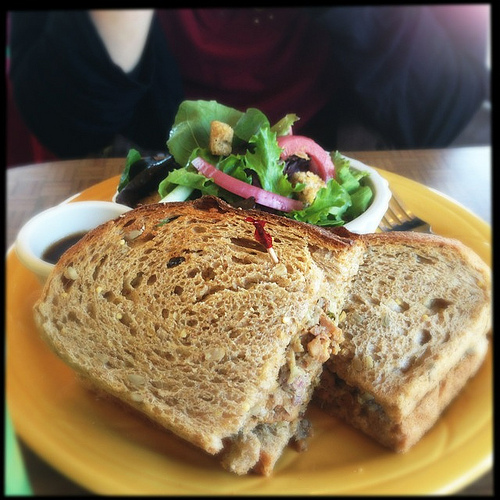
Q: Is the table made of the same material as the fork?
A: No, the table is made of wood and the fork is made of metal.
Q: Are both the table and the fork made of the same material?
A: No, the table is made of wood and the fork is made of metal.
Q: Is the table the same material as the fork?
A: No, the table is made of wood and the fork is made of metal.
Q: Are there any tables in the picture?
A: Yes, there is a table.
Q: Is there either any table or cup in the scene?
A: Yes, there is a table.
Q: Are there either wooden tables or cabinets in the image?
A: Yes, there is a wood table.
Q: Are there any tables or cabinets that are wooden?
A: Yes, the table is wooden.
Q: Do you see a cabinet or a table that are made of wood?
A: Yes, the table is made of wood.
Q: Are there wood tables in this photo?
A: Yes, there is a wood table.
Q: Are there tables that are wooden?
A: Yes, there is a table that is wooden.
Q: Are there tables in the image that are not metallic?
A: Yes, there is a wooden table.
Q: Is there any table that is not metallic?
A: Yes, there is a wooden table.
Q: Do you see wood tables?
A: Yes, there is a table that is made of wood.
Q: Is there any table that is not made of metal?
A: Yes, there is a table that is made of wood.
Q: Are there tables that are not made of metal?
A: Yes, there is a table that is made of wood.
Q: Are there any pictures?
A: No, there are no pictures.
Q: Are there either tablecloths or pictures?
A: No, there are no pictures or tablecloths.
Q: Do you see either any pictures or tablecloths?
A: No, there are no pictures or tablecloths.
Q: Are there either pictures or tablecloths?
A: No, there are no pictures or tablecloths.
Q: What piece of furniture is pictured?
A: The piece of furniture is a table.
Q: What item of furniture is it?
A: The piece of furniture is a table.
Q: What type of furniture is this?
A: This is a table.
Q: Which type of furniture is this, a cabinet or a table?
A: This is a table.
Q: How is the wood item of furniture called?
A: The piece of furniture is a table.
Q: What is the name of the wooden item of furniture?
A: The piece of furniture is a table.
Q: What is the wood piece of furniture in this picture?
A: The piece of furniture is a table.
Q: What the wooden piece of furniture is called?
A: The piece of furniture is a table.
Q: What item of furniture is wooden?
A: The piece of furniture is a table.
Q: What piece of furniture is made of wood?
A: The piece of furniture is a table.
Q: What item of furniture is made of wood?
A: The piece of furniture is a table.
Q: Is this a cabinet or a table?
A: This is a table.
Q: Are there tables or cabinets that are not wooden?
A: No, there is a table but it is wooden.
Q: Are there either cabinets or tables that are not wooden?
A: No, there is a table but it is wooden.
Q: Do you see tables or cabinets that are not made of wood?
A: No, there is a table but it is made of wood.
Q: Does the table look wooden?
A: Yes, the table is wooden.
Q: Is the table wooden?
A: Yes, the table is wooden.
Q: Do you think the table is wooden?
A: Yes, the table is wooden.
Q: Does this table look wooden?
A: Yes, the table is wooden.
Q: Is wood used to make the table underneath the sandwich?
A: Yes, the table is made of wood.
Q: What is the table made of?
A: The table is made of wood.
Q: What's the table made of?
A: The table is made of wood.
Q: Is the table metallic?
A: No, the table is wooden.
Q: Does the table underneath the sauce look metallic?
A: No, the table is wooden.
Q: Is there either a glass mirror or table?
A: No, there is a table but it is wooden.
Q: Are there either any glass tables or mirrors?
A: No, there is a table but it is wooden.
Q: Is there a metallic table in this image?
A: No, there is a table but it is wooden.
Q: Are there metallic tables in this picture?
A: No, there is a table but it is wooden.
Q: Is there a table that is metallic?
A: No, there is a table but it is wooden.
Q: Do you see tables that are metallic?
A: No, there is a table but it is wooden.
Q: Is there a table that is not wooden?
A: No, there is a table but it is wooden.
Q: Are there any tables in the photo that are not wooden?
A: No, there is a table but it is wooden.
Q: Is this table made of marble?
A: No, the table is made of wood.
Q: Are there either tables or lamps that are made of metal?
A: No, there is a table but it is made of wood.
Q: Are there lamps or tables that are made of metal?
A: No, there is a table but it is made of wood.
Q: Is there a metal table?
A: No, there is a table but it is made of wood.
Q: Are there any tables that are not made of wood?
A: No, there is a table but it is made of wood.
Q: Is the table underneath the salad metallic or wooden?
A: The table is wooden.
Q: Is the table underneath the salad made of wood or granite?
A: The table is made of wood.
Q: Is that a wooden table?
A: Yes, that is a wooden table.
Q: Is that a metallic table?
A: No, that is a wooden table.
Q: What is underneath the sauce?
A: The table is underneath the sauce.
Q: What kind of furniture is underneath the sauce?
A: The piece of furniture is a table.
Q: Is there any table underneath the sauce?
A: Yes, there is a table underneath the sauce.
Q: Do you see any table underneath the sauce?
A: Yes, there is a table underneath the sauce.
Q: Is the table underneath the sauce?
A: Yes, the table is underneath the sauce.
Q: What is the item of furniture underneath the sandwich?
A: The piece of furniture is a table.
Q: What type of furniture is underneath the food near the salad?
A: The piece of furniture is a table.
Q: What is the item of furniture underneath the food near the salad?
A: The piece of furniture is a table.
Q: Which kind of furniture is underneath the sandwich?
A: The piece of furniture is a table.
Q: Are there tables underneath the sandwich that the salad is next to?
A: Yes, there is a table underneath the sandwich.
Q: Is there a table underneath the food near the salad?
A: Yes, there is a table underneath the sandwich.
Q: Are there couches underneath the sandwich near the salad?
A: No, there is a table underneath the sandwich.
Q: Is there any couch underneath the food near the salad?
A: No, there is a table underneath the sandwich.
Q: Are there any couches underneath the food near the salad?
A: No, there is a table underneath the sandwich.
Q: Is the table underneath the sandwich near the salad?
A: Yes, the table is underneath the sandwich.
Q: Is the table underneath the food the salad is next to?
A: Yes, the table is underneath the sandwich.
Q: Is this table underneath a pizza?
A: No, the table is underneath the sandwich.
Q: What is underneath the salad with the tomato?
A: The table is underneath the salad.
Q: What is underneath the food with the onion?
A: The table is underneath the salad.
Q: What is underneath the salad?
A: The table is underneath the salad.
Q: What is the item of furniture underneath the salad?
A: The piece of furniture is a table.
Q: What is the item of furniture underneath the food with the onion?
A: The piece of furniture is a table.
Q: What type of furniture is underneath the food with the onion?
A: The piece of furniture is a table.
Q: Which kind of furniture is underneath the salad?
A: The piece of furniture is a table.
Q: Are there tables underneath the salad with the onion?
A: Yes, there is a table underneath the salad.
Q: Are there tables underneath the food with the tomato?
A: Yes, there is a table underneath the salad.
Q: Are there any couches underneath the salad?
A: No, there is a table underneath the salad.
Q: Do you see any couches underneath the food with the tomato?
A: No, there is a table underneath the salad.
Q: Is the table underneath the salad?
A: Yes, the table is underneath the salad.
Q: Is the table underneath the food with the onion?
A: Yes, the table is underneath the salad.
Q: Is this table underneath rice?
A: No, the table is underneath the salad.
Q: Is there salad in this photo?
A: Yes, there is salad.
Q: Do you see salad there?
A: Yes, there is salad.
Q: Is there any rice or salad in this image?
A: Yes, there is salad.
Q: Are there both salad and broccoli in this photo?
A: No, there is salad but no broccoli.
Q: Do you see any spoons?
A: No, there are no spoons.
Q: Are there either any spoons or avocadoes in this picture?
A: No, there are no spoons or avocadoes.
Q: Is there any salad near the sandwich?
A: Yes, there is salad near the sandwich.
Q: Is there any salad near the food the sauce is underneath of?
A: Yes, there is salad near the sandwich.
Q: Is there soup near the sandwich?
A: No, there is salad near the sandwich.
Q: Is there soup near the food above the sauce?
A: No, there is salad near the sandwich.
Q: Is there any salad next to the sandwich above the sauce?
A: Yes, there is salad next to the sandwich.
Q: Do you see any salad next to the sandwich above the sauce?
A: Yes, there is salad next to the sandwich.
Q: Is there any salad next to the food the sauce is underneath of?
A: Yes, there is salad next to the sandwich.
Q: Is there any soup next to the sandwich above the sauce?
A: No, there is salad next to the sandwich.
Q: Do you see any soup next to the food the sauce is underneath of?
A: No, there is salad next to the sandwich.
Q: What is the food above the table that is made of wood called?
A: The food is salad.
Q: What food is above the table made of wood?
A: The food is salad.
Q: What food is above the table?
A: The food is salad.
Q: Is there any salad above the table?
A: Yes, there is salad above the table.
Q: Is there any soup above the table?
A: No, there is salad above the table.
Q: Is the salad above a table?
A: Yes, the salad is above a table.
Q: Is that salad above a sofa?
A: No, the salad is above a table.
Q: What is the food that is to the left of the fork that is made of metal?
A: The food is salad.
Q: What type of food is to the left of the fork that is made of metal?
A: The food is salad.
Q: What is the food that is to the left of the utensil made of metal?
A: The food is salad.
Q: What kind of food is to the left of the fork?
A: The food is salad.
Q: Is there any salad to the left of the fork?
A: Yes, there is salad to the left of the fork.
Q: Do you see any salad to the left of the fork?
A: Yes, there is salad to the left of the fork.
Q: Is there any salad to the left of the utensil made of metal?
A: Yes, there is salad to the left of the fork.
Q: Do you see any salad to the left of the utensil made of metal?
A: Yes, there is salad to the left of the fork.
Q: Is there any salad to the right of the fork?
A: No, the salad is to the left of the fork.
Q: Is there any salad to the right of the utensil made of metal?
A: No, the salad is to the left of the fork.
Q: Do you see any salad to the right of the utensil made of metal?
A: No, the salad is to the left of the fork.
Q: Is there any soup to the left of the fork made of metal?
A: No, there is salad to the left of the fork.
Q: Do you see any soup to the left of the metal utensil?
A: No, there is salad to the left of the fork.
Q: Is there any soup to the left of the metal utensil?
A: No, there is salad to the left of the fork.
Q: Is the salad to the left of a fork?
A: Yes, the salad is to the left of a fork.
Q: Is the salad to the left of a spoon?
A: No, the salad is to the left of a fork.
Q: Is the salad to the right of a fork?
A: No, the salad is to the left of a fork.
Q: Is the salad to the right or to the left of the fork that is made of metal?
A: The salad is to the left of the fork.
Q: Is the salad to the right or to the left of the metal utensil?
A: The salad is to the left of the fork.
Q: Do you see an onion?
A: Yes, there is an onion.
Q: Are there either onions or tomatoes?
A: Yes, there is an onion.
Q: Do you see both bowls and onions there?
A: Yes, there are both an onion and a bowl.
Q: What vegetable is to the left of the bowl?
A: The vegetable is an onion.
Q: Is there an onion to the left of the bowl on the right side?
A: Yes, there is an onion to the left of the bowl.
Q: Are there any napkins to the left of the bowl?
A: No, there is an onion to the left of the bowl.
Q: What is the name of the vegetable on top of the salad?
A: The vegetable is an onion.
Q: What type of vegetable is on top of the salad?
A: The vegetable is an onion.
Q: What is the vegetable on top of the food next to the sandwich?
A: The vegetable is an onion.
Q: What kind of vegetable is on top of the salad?
A: The vegetable is an onion.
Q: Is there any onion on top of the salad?
A: Yes, there is an onion on top of the salad.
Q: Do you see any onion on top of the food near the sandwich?
A: Yes, there is an onion on top of the salad.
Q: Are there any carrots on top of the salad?
A: No, there is an onion on top of the salad.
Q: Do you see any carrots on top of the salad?
A: No, there is an onion on top of the salad.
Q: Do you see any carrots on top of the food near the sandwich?
A: No, there is an onion on top of the salad.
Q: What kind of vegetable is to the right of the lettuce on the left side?
A: The vegetable is an onion.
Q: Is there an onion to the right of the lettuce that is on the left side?
A: Yes, there is an onion to the right of the lettuce.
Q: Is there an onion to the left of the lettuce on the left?
A: No, the onion is to the right of the lettuce.